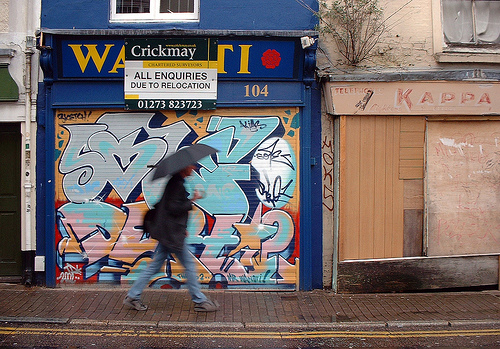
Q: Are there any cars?
A: No, there are no cars.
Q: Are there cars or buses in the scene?
A: No, there are no cars or buses.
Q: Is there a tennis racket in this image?
A: No, there are no rackets.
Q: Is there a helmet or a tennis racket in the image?
A: No, there are no rackets or helmets.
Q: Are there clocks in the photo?
A: No, there are no clocks.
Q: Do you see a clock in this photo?
A: No, there are no clocks.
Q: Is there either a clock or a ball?
A: No, there are no clocks or balls.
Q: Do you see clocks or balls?
A: No, there are no clocks or balls.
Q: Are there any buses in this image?
A: No, there are no buses.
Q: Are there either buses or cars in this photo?
A: No, there are no buses or cars.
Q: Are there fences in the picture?
A: No, there are no fences.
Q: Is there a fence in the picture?
A: No, there are no fences.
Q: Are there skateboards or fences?
A: No, there are no fences or skateboards.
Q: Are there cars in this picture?
A: No, there are no cars.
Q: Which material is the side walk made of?
A: The side walk is made of brick.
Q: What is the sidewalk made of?
A: The side walk is made of brick.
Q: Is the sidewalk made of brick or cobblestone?
A: The sidewalk is made of brick.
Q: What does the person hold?
A: The person holds the umbrella.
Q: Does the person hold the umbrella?
A: Yes, the person holds the umbrella.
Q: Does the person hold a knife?
A: No, the person holds the umbrella.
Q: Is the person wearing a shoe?
A: Yes, the person is wearing a shoe.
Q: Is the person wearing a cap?
A: No, the person is wearing a shoe.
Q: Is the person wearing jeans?
A: Yes, the person is wearing jeans.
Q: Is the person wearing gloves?
A: No, the person is wearing jeans.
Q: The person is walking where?
A: The person is walking on the sidewalk.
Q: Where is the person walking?
A: The person is walking on the sidewalk.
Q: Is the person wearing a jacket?
A: Yes, the person is wearing a jacket.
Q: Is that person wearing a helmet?
A: No, the person is wearing a jacket.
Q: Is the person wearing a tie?
A: No, the person is wearing a shoe.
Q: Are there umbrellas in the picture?
A: Yes, there is an umbrella.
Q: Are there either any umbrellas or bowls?
A: Yes, there is an umbrella.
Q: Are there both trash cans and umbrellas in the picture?
A: No, there is an umbrella but no trash cans.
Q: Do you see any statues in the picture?
A: No, there are no statues.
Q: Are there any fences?
A: No, there are no fences.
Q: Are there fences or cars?
A: No, there are no fences or cars.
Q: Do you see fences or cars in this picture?
A: No, there are no fences or cars.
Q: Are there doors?
A: Yes, there is a door.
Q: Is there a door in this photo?
A: Yes, there is a door.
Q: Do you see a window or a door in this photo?
A: Yes, there is a door.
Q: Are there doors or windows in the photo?
A: Yes, there is a door.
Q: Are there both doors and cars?
A: No, there is a door but no cars.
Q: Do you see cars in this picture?
A: No, there are no cars.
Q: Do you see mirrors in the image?
A: No, there are no mirrors.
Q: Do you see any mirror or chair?
A: No, there are no mirrors or chairs.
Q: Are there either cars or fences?
A: No, there are no cars or fences.